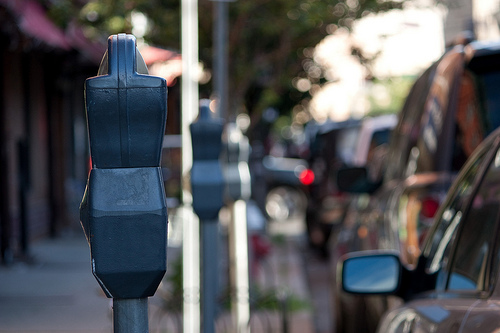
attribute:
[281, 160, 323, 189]
light — rear, lit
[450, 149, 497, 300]
window — rear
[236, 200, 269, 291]
hydrant — red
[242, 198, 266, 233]
cap — white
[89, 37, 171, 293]
meter — for parking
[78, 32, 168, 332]
meter — black 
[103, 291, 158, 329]
pole — metal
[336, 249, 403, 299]
mirror — sideview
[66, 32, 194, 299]
meter — grey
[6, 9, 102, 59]
roof — red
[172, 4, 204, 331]
pole — white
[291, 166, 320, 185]
glare — Red 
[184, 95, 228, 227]
parking meter — grey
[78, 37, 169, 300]
parking meter — grey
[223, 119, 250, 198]
parking meter — grey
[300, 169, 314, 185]
circle — red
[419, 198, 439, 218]
circle — red